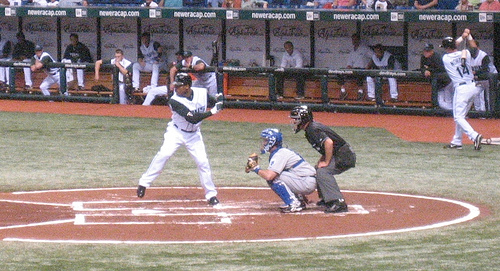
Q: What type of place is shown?
A: It is a field.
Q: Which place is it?
A: It is a field.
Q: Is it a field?
A: Yes, it is a field.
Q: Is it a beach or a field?
A: It is a field.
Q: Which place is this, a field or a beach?
A: It is a field.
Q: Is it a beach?
A: No, it is a field.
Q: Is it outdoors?
A: Yes, it is outdoors.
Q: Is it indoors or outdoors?
A: It is outdoors.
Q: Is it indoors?
A: No, it is outdoors.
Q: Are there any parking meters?
A: No, there are no parking meters.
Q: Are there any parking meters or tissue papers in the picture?
A: No, there are no parking meters or tissue papers.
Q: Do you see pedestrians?
A: No, there are no pedestrians.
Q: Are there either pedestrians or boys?
A: No, there are no pedestrians or boys.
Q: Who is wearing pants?
A: The man is wearing pants.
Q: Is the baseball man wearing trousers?
A: Yes, the man is wearing trousers.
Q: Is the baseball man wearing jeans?
A: No, the man is wearing trousers.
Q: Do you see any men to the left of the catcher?
A: Yes, there is a man to the left of the catcher.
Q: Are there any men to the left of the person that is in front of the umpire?
A: Yes, there is a man to the left of the catcher.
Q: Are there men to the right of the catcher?
A: No, the man is to the left of the catcher.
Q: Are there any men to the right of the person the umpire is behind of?
A: No, the man is to the left of the catcher.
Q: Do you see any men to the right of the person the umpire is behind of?
A: No, the man is to the left of the catcher.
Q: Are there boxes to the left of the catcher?
A: No, there is a man to the left of the catcher.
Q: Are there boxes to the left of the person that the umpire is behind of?
A: No, there is a man to the left of the catcher.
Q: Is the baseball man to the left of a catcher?
A: Yes, the man is to the left of a catcher.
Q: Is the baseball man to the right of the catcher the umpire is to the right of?
A: No, the man is to the left of the catcher.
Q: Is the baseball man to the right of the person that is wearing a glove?
A: No, the man is to the left of the catcher.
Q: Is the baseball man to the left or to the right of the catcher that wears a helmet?
A: The man is to the left of the catcher.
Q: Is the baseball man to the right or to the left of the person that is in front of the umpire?
A: The man is to the left of the catcher.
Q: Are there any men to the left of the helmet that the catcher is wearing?
A: Yes, there is a man to the left of the helmet.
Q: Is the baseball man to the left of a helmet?
A: Yes, the man is to the left of a helmet.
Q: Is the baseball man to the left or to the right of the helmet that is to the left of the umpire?
A: The man is to the left of the helmet.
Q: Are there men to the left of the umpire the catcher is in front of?
A: Yes, there is a man to the left of the umpire.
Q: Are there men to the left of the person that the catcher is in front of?
A: Yes, there is a man to the left of the umpire.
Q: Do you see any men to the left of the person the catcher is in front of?
A: Yes, there is a man to the left of the umpire.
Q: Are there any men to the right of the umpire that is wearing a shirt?
A: No, the man is to the left of the umpire.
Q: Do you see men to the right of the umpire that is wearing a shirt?
A: No, the man is to the left of the umpire.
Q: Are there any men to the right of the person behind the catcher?
A: No, the man is to the left of the umpire.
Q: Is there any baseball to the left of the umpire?
A: No, there is a man to the left of the umpire.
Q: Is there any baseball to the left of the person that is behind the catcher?
A: No, there is a man to the left of the umpire.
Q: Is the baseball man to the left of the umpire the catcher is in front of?
A: Yes, the man is to the left of the umpire.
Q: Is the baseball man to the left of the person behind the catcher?
A: Yes, the man is to the left of the umpire.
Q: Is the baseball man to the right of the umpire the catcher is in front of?
A: No, the man is to the left of the umpire.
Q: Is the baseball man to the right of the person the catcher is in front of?
A: No, the man is to the left of the umpire.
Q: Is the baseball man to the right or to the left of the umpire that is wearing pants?
A: The man is to the left of the umpire.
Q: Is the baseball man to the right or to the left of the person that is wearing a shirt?
A: The man is to the left of the umpire.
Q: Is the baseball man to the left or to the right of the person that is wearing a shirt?
A: The man is to the left of the umpire.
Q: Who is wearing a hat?
A: The man is wearing a hat.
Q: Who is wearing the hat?
A: The man is wearing a hat.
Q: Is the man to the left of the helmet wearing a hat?
A: Yes, the man is wearing a hat.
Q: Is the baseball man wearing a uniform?
A: No, the man is wearing a hat.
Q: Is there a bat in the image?
A: Yes, there is a bat.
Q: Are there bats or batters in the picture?
A: Yes, there is a bat.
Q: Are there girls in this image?
A: No, there are no girls.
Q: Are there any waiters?
A: No, there are no waiters.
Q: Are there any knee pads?
A: No, there are no knee pads.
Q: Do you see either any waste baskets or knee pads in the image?
A: No, there are no knee pads or waste baskets.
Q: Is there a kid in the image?
A: No, there are no children.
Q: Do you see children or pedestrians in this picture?
A: No, there are no children or pedestrians.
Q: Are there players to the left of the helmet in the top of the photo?
A: Yes, there is a player to the left of the helmet.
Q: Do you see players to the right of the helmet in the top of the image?
A: No, the player is to the left of the helmet.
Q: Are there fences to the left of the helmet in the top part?
A: No, there is a player to the left of the helmet.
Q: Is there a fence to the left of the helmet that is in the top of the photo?
A: No, there is a player to the left of the helmet.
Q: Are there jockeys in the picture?
A: No, there are no jockeys.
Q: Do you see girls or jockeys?
A: No, there are no jockeys or girls.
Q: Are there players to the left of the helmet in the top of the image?
A: Yes, there is a player to the left of the helmet.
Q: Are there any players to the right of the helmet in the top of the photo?
A: No, the player is to the left of the helmet.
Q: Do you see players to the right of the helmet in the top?
A: No, the player is to the left of the helmet.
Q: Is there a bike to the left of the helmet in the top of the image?
A: No, there is a player to the left of the helmet.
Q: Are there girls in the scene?
A: No, there are no girls.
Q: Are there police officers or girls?
A: No, there are no girls or police officers.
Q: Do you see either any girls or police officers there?
A: No, there are no girls or police officers.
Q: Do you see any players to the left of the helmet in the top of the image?
A: Yes, there is a player to the left of the helmet.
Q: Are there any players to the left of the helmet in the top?
A: Yes, there is a player to the left of the helmet.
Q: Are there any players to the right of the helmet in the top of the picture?
A: No, the player is to the left of the helmet.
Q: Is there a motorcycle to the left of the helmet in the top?
A: No, there is a player to the left of the helmet.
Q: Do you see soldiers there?
A: No, there are no soldiers.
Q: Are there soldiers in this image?
A: No, there are no soldiers.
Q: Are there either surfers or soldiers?
A: No, there are no soldiers or surfers.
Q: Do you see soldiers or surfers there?
A: No, there are no soldiers or surfers.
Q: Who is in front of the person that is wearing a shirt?
A: The catcher is in front of the umpire.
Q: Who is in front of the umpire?
A: The catcher is in front of the umpire.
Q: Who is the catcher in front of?
A: The catcher is in front of the umpire.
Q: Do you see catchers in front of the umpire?
A: Yes, there is a catcher in front of the umpire.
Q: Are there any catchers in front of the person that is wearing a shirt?
A: Yes, there is a catcher in front of the umpire.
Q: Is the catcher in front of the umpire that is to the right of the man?
A: Yes, the catcher is in front of the umpire.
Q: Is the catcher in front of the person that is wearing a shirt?
A: Yes, the catcher is in front of the umpire.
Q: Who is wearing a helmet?
A: The catcher is wearing a helmet.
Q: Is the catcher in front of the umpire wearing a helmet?
A: Yes, the catcher is wearing a helmet.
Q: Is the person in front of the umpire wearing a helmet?
A: Yes, the catcher is wearing a helmet.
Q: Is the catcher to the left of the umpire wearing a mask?
A: No, the catcher is wearing a helmet.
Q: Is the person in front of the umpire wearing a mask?
A: No, the catcher is wearing a helmet.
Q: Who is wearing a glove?
A: The catcher is wearing a glove.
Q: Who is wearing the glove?
A: The catcher is wearing a glove.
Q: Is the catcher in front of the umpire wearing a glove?
A: Yes, the catcher is wearing a glove.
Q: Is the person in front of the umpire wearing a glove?
A: Yes, the catcher is wearing a glove.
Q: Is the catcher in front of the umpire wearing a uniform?
A: No, the catcher is wearing a glove.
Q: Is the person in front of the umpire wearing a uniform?
A: No, the catcher is wearing a glove.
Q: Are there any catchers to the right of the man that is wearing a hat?
A: Yes, there is a catcher to the right of the man.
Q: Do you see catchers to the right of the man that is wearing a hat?
A: Yes, there is a catcher to the right of the man.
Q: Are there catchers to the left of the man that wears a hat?
A: No, the catcher is to the right of the man.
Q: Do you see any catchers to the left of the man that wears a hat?
A: No, the catcher is to the right of the man.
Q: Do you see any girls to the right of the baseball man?
A: No, there is a catcher to the right of the man.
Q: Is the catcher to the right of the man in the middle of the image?
A: Yes, the catcher is to the right of the man.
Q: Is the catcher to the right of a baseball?
A: No, the catcher is to the right of the man.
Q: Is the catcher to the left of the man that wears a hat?
A: No, the catcher is to the right of the man.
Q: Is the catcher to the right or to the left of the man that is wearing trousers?
A: The catcher is to the right of the man.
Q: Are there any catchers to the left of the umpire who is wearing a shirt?
A: Yes, there is a catcher to the left of the umpire.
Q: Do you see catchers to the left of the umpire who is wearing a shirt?
A: Yes, there is a catcher to the left of the umpire.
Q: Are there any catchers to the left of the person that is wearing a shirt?
A: Yes, there is a catcher to the left of the umpire.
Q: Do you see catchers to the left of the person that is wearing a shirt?
A: Yes, there is a catcher to the left of the umpire.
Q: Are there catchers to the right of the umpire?
A: No, the catcher is to the left of the umpire.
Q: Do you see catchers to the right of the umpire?
A: No, the catcher is to the left of the umpire.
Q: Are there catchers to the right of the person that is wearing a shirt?
A: No, the catcher is to the left of the umpire.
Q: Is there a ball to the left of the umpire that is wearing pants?
A: No, there is a catcher to the left of the umpire.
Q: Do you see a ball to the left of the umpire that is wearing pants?
A: No, there is a catcher to the left of the umpire.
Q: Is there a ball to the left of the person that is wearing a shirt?
A: No, there is a catcher to the left of the umpire.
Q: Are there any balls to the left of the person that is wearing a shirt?
A: No, there is a catcher to the left of the umpire.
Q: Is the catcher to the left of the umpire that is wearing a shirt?
A: Yes, the catcher is to the left of the umpire.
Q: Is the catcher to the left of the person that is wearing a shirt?
A: Yes, the catcher is to the left of the umpire.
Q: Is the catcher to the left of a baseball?
A: No, the catcher is to the left of the umpire.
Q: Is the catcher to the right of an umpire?
A: No, the catcher is to the left of an umpire.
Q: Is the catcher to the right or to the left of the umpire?
A: The catcher is to the left of the umpire.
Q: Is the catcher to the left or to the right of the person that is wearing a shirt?
A: The catcher is to the left of the umpire.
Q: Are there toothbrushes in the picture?
A: No, there are no toothbrushes.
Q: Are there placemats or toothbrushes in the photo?
A: No, there are no toothbrushes or placemats.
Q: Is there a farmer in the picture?
A: No, there are no farmers.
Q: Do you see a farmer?
A: No, there are no farmers.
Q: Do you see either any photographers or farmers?
A: No, there are no farmers or photographers.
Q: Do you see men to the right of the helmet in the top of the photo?
A: Yes, there is a man to the right of the helmet.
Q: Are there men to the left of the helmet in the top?
A: No, the man is to the right of the helmet.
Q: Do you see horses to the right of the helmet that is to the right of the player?
A: No, there is a man to the right of the helmet.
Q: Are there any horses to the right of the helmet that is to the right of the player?
A: No, there is a man to the right of the helmet.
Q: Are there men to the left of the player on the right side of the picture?
A: Yes, there is a man to the left of the player.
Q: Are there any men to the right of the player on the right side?
A: No, the man is to the left of the player.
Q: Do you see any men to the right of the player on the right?
A: No, the man is to the left of the player.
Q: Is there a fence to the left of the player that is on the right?
A: No, there is a man to the left of the player.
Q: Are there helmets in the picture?
A: Yes, there is a helmet.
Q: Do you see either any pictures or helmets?
A: Yes, there is a helmet.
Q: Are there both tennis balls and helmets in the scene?
A: No, there is a helmet but no tennis balls.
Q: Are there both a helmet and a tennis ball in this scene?
A: No, there is a helmet but no tennis balls.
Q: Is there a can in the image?
A: No, there are no cans.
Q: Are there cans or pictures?
A: No, there are no cans or pictures.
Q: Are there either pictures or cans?
A: No, there are no cans or pictures.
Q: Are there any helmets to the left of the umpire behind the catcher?
A: Yes, there is a helmet to the left of the umpire.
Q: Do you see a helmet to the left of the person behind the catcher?
A: Yes, there is a helmet to the left of the umpire.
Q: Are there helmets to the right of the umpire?
A: No, the helmet is to the left of the umpire.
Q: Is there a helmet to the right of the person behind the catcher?
A: No, the helmet is to the left of the umpire.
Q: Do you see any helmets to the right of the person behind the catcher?
A: No, the helmet is to the left of the umpire.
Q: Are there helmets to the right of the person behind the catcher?
A: No, the helmet is to the left of the umpire.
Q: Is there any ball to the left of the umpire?
A: No, there is a helmet to the left of the umpire.